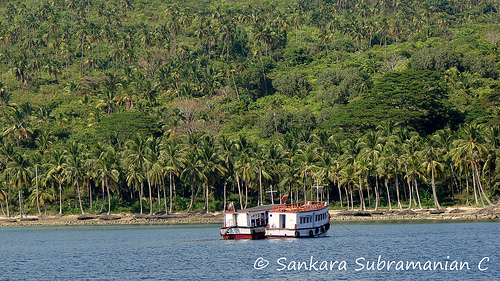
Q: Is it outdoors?
A: Yes, it is outdoors.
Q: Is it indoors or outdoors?
A: It is outdoors.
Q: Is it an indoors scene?
A: No, it is outdoors.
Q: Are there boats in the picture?
A: Yes, there is a boat.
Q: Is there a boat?
A: Yes, there is a boat.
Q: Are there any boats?
A: Yes, there is a boat.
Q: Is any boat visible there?
A: Yes, there is a boat.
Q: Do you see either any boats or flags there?
A: Yes, there is a boat.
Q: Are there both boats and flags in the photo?
A: Yes, there are both a boat and a flag.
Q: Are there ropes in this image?
A: No, there are no ropes.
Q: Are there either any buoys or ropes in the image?
A: No, there are no ropes or buoys.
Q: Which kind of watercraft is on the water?
A: The watercraft is a boat.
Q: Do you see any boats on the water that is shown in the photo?
A: Yes, there is a boat on the water.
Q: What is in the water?
A: The boat is in the water.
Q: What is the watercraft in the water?
A: The watercraft is a boat.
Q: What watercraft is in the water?
A: The watercraft is a boat.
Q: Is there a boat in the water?
A: Yes, there is a boat in the water.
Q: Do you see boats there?
A: Yes, there is a boat.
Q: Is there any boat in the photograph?
A: Yes, there is a boat.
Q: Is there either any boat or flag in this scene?
A: Yes, there is a boat.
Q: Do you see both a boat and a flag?
A: Yes, there are both a boat and a flag.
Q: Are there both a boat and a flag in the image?
A: Yes, there are both a boat and a flag.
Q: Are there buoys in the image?
A: No, there are no buoys.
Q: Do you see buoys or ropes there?
A: No, there are no buoys or ropes.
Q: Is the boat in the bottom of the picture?
A: Yes, the boat is in the bottom of the image.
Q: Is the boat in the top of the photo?
A: No, the boat is in the bottom of the image.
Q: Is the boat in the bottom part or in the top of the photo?
A: The boat is in the bottom of the image.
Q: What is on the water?
A: The boat is on the water.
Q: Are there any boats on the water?
A: Yes, there is a boat on the water.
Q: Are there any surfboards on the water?
A: No, there is a boat on the water.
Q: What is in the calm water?
A: The boat is in the water.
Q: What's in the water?
A: The boat is in the water.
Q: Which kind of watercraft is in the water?
A: The watercraft is a boat.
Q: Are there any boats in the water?
A: Yes, there is a boat in the water.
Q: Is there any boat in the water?
A: Yes, there is a boat in the water.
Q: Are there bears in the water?
A: No, there is a boat in the water.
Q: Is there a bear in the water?
A: No, there is a boat in the water.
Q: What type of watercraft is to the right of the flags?
A: The watercraft is a boat.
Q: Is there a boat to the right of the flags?
A: Yes, there is a boat to the right of the flags.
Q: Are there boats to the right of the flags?
A: Yes, there is a boat to the right of the flags.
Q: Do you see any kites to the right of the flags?
A: No, there is a boat to the right of the flags.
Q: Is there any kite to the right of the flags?
A: No, there is a boat to the right of the flags.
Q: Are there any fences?
A: No, there are no fences.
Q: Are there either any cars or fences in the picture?
A: No, there are no fences or cars.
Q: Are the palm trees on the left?
A: Yes, the palm trees are on the left of the image.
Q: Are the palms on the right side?
A: No, the palms are on the left of the image.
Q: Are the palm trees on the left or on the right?
A: The palm trees are on the left of the image.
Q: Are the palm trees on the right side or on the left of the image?
A: The palm trees are on the left of the image.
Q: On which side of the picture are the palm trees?
A: The palm trees are on the left of the image.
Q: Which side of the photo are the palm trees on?
A: The palm trees are on the left of the image.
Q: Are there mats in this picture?
A: No, there are no mats.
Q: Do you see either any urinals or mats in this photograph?
A: No, there are no mats or urinals.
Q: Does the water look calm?
A: Yes, the water is calm.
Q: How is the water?
A: The water is calm.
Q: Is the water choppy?
A: No, the water is calm.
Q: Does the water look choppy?
A: No, the water is calm.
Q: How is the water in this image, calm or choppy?
A: The water is calm.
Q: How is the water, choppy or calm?
A: The water is calm.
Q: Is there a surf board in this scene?
A: No, there are no surfboards.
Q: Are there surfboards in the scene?
A: No, there are no surfboards.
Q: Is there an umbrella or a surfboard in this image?
A: No, there are no surfboards or umbrellas.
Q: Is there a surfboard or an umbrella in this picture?
A: No, there are no surfboards or umbrellas.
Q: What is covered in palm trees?
A: The beach is covered in palm trees.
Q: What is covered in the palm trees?
A: The beach is covered in palm trees.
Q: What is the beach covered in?
A: The beach is covered in palm trees.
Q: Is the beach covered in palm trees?
A: Yes, the beach is covered in palm trees.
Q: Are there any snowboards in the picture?
A: No, there are no snowboards.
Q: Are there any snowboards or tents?
A: No, there are no snowboards or tents.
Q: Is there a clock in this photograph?
A: No, there are no clocks.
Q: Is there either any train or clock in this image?
A: No, there are no clocks or trains.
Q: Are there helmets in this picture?
A: No, there are no helmets.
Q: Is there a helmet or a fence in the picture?
A: No, there are no helmets or fences.